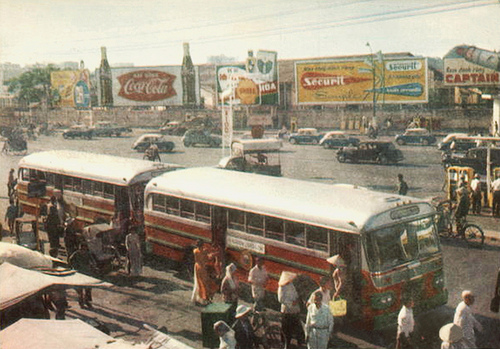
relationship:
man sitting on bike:
[448, 177, 470, 243] [436, 201, 484, 245]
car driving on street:
[335, 140, 406, 164] [18, 127, 498, 282]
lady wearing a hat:
[326, 254, 353, 323] [323, 253, 345, 265]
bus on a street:
[13, 150, 186, 237] [17, 128, 499, 337]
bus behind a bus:
[13, 150, 175, 243] [147, 173, 454, 320]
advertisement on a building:
[100, 62, 195, 107] [92, 49, 222, 134]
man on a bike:
[454, 186, 471, 239] [425, 205, 492, 254]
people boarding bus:
[181, 233, 223, 310] [143, 165, 453, 333]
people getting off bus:
[181, 233, 223, 310] [143, 165, 453, 333]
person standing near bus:
[116, 213, 146, 278] [143, 165, 453, 333]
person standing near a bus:
[223, 260, 240, 303] [143, 165, 453, 333]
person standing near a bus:
[276, 270, 305, 349] [143, 165, 453, 333]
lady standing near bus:
[326, 254, 353, 323] [143, 165, 453, 333]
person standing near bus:
[389, 289, 423, 347] [143, 165, 453, 333]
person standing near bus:
[440, 322, 476, 347] [143, 165, 453, 333]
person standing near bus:
[395, 296, 415, 348] [143, 165, 453, 333]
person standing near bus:
[302, 291, 333, 344] [143, 165, 453, 333]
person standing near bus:
[307, 274, 332, 307] [143, 165, 453, 333]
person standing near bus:
[276, 268, 305, 347] [143, 165, 453, 333]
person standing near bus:
[454, 290, 488, 347] [144, 172, 439, 328]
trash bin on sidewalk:
[201, 296, 239, 346] [78, 235, 202, 347]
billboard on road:
[49, 67, 93, 108] [10, 104, 498, 133]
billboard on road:
[95, 42, 198, 107] [10, 104, 498, 133]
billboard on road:
[216, 46, 281, 107] [10, 104, 498, 133]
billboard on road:
[294, 55, 429, 105] [10, 104, 498, 133]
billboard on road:
[443, 44, 499, 86] [10, 104, 498, 133]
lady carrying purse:
[321, 253, 353, 325] [324, 294, 348, 321]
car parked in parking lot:
[435, 134, 498, 155] [4, 124, 498, 322]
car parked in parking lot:
[335, 140, 406, 164] [4, 124, 498, 322]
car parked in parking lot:
[133, 134, 180, 152] [4, 124, 498, 322]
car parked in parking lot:
[60, 124, 105, 140] [4, 124, 498, 322]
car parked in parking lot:
[286, 127, 326, 147] [4, 124, 498, 322]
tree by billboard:
[6, 57, 72, 105] [44, 68, 90, 110]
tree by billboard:
[6, 57, 72, 105] [209, 60, 285, 104]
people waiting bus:
[190, 238, 220, 307] [143, 165, 453, 333]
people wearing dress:
[190, 238, 220, 307] [193, 263, 212, 308]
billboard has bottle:
[95, 42, 201, 107] [94, 47, 117, 108]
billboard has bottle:
[95, 42, 201, 107] [181, 44, 198, 107]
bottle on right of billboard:
[141, 36, 263, 111] [95, 42, 201, 107]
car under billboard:
[335, 140, 405, 163] [294, 55, 429, 105]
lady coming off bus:
[326, 254, 353, 323] [143, 165, 453, 333]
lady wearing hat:
[326, 254, 353, 323] [325, 251, 347, 266]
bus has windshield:
[143, 165, 453, 333] [364, 215, 437, 266]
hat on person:
[277, 269, 298, 288] [276, 270, 305, 349]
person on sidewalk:
[276, 270, 305, 349] [0, 200, 393, 346]